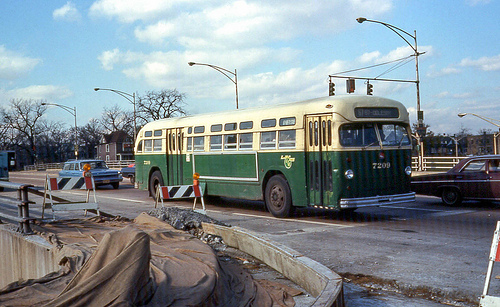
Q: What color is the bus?
A: Green and cream.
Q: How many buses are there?
A: 1.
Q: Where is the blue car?
A: Behind the bus.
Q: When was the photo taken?
A: Day time.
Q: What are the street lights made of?
A: Metal.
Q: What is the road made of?
A: Tarmac.